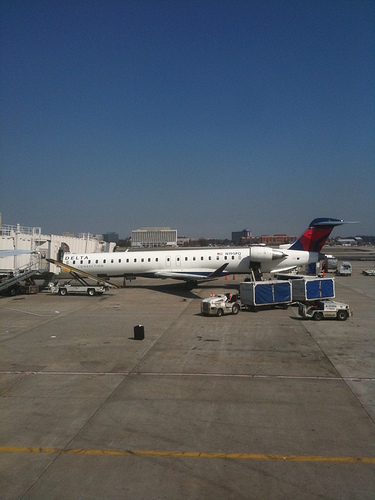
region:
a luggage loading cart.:
[188, 264, 340, 327]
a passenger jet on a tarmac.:
[57, 211, 360, 287]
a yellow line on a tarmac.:
[0, 442, 374, 463]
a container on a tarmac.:
[128, 316, 152, 342]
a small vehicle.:
[290, 296, 354, 327]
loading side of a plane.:
[162, 252, 185, 282]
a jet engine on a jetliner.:
[243, 244, 290, 280]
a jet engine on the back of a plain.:
[294, 247, 325, 274]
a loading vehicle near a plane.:
[32, 252, 116, 303]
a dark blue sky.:
[0, 0, 369, 236]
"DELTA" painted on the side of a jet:
[60, 252, 86, 259]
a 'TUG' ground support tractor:
[292, 295, 352, 319]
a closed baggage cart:
[237, 276, 292, 310]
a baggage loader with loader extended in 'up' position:
[38, 255, 115, 296]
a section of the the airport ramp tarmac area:
[0, 338, 371, 495]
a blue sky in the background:
[0, 0, 372, 213]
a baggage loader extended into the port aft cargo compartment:
[245, 260, 262, 278]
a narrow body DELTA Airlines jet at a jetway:
[52, 212, 356, 272]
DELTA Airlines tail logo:
[291, 222, 333, 254]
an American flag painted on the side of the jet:
[216, 250, 224, 255]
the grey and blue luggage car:
[240, 277, 293, 309]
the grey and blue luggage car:
[294, 270, 335, 303]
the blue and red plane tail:
[294, 210, 344, 251]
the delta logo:
[63, 253, 90, 262]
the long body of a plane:
[65, 242, 331, 275]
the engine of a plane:
[249, 245, 285, 259]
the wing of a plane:
[156, 259, 228, 289]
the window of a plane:
[116, 256, 122, 264]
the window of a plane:
[207, 255, 212, 261]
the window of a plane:
[72, 258, 76, 264]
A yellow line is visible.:
[106, 414, 266, 493]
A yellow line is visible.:
[114, 350, 327, 494]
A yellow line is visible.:
[73, 396, 196, 486]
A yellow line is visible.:
[91, 378, 260, 470]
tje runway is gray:
[102, 360, 365, 446]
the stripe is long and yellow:
[35, 435, 356, 483]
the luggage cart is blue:
[233, 273, 346, 304]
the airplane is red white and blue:
[64, 214, 367, 273]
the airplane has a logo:
[291, 227, 334, 250]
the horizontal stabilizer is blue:
[306, 213, 362, 233]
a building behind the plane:
[124, 222, 184, 246]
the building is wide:
[124, 219, 178, 245]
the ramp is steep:
[3, 256, 51, 288]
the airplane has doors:
[163, 251, 182, 270]